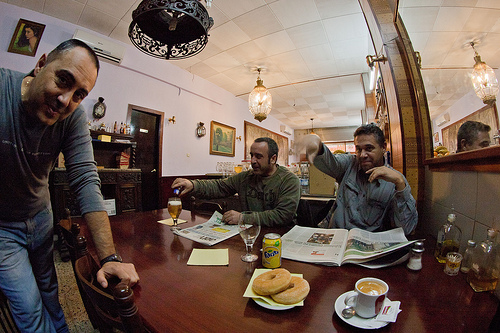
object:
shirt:
[1, 64, 111, 226]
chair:
[62, 220, 146, 332]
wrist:
[95, 250, 120, 267]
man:
[0, 29, 134, 333]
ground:
[405, 162, 460, 202]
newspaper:
[280, 224, 419, 269]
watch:
[89, 252, 132, 268]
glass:
[164, 197, 182, 229]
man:
[167, 136, 297, 226]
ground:
[456, 109, 472, 122]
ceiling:
[0, 0, 499, 129]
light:
[242, 80, 278, 122]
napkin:
[185, 245, 227, 267]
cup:
[346, 276, 391, 322]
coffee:
[361, 279, 381, 299]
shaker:
[406, 237, 427, 270]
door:
[128, 98, 164, 220]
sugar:
[378, 303, 403, 321]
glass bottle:
[436, 211, 463, 267]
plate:
[251, 272, 299, 312]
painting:
[8, 19, 46, 56]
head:
[26, 38, 99, 125]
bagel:
[257, 269, 308, 302]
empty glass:
[235, 210, 264, 267]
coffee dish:
[335, 280, 399, 330]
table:
[84, 204, 499, 331]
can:
[262, 231, 283, 271]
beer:
[166, 199, 183, 220]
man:
[295, 121, 421, 238]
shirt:
[190, 165, 301, 231]